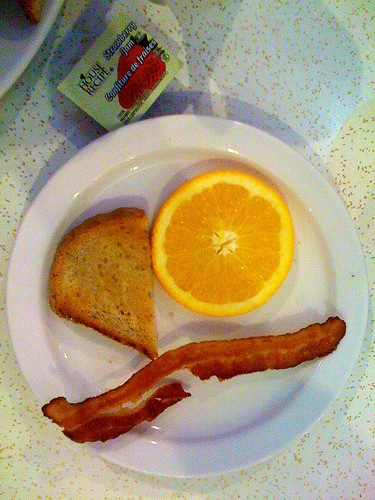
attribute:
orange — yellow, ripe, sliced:
[145, 161, 316, 328]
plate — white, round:
[8, 121, 366, 495]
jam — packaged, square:
[56, 16, 190, 136]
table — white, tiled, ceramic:
[192, 1, 374, 103]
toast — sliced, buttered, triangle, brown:
[49, 205, 152, 365]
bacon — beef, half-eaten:
[45, 319, 355, 458]